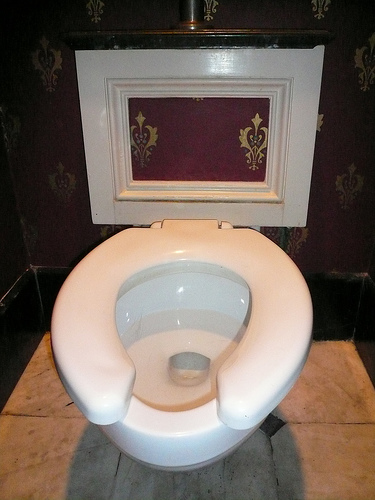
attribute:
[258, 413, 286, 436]
spot — black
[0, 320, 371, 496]
tile — white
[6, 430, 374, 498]
floor — tile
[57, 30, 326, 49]
tank cover — black, toilet tank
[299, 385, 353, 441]
tile — stone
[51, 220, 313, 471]
toilet bowl — white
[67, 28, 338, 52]
blacklid — black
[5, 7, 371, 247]
wall — back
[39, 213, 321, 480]
toilet — white, clean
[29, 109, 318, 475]
toilet — white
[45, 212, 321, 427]
seat — white, toilet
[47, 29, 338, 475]
toilet — very clean, white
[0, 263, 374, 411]
baseboards — dusty, black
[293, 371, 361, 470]
tile — white, cracked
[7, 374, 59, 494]
floor — bathroom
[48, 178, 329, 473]
toilet — clean, bathroom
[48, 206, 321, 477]
white toilet — inside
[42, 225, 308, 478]
toilet — white, bathroom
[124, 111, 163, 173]
design — golden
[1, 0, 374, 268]
wallpaper — red, golden, dark red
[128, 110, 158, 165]
design — dark decorative, golden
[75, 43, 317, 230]
frame — white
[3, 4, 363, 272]
wall — red